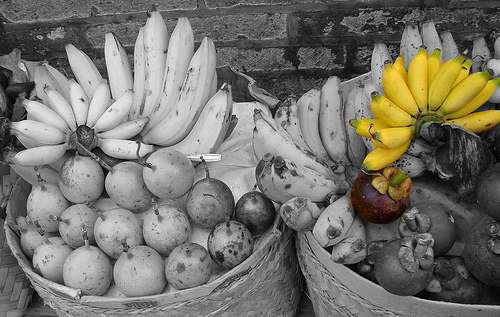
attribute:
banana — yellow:
[368, 124, 410, 149]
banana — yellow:
[424, 50, 466, 110]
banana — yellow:
[423, 51, 464, 116]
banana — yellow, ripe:
[351, 49, 497, 166]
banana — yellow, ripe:
[10, 10, 230, 171]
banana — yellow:
[347, 110, 423, 177]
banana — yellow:
[403, 46, 432, 117]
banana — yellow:
[315, 45, 487, 185]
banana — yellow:
[418, 31, 446, 111]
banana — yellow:
[376, 98, 429, 123]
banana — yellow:
[326, 61, 486, 149]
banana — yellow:
[438, 61, 493, 113]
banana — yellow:
[362, 143, 412, 169]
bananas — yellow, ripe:
[353, 118, 428, 148]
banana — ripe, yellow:
[373, 129, 414, 146]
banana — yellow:
[379, 55, 419, 117]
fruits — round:
[71, 150, 202, 244]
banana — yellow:
[342, 50, 498, 195]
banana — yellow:
[330, 41, 472, 171]